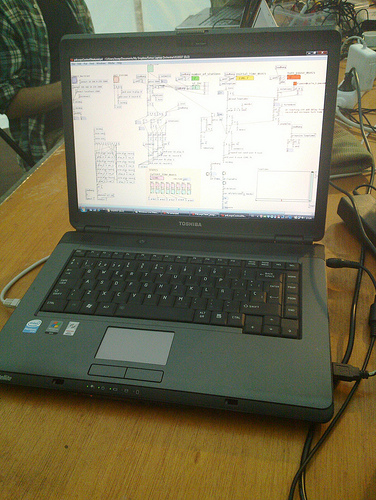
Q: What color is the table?
A: Brown.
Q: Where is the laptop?
A: On a desk.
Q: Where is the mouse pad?
A: On the laptop.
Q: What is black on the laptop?
A: Keys.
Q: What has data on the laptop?
A: The screen.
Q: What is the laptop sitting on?
A: Wooden desk.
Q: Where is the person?
A: Behind the desk.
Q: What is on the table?
A: An open laptop.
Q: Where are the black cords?
A: They are plugged into laptop.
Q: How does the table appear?
A: Wooden.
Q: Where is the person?
A: Near the table.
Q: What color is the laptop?
A: Grey.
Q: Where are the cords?
A: Beside the laptop.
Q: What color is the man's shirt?
A: Green.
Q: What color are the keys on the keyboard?
A: Black.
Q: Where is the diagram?
A: On the laptop screen.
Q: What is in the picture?
A: A laptop.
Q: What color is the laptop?
A: Black.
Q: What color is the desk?
A: Brown.